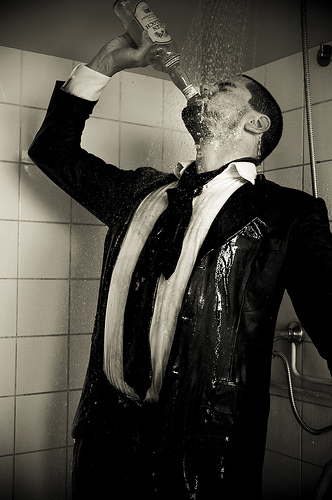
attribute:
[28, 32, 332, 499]
man — showering, drinking, wet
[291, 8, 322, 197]
hose — hanging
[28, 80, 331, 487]
jacket — wet, black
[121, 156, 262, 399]
tie — messy, knotted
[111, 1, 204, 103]
bottle — glass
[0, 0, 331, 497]
wall — tiled, shadowy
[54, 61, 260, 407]
shirt — long, white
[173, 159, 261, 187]
collar — open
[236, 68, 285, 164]
hair — short, dark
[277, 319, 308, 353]
handle — silver, metal